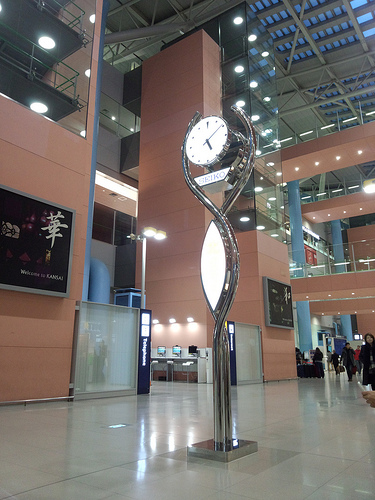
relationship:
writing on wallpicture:
[39, 203, 68, 256] [8, 187, 69, 295]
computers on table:
[158, 343, 203, 358] [154, 356, 197, 366]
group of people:
[296, 332, 374, 377] [294, 343, 373, 369]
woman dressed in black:
[358, 332, 372, 395] [355, 343, 374, 387]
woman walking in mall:
[358, 332, 372, 395] [1, 2, 367, 485]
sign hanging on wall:
[8, 187, 69, 295] [2, 97, 80, 402]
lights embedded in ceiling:
[235, 19, 278, 63] [117, 5, 374, 113]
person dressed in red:
[350, 342, 363, 374] [354, 343, 361, 369]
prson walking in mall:
[352, 342, 362, 374] [1, 2, 367, 485]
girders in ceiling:
[291, 68, 374, 97] [117, 5, 374, 113]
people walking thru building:
[294, 343, 373, 369] [1, 2, 367, 485]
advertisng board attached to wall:
[8, 187, 69, 295] [2, 97, 80, 402]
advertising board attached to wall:
[8, 187, 69, 295] [2, 97, 80, 402]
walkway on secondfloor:
[6, 35, 85, 108] [2, 48, 82, 91]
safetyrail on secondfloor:
[6, 35, 85, 108] [2, 48, 82, 91]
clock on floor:
[180, 116, 253, 166] [47, 406, 360, 481]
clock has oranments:
[180, 116, 253, 166] [195, 123, 235, 149]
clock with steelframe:
[180, 116, 253, 166] [185, 105, 246, 458]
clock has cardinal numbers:
[180, 116, 253, 166] [186, 125, 200, 162]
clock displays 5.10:
[180, 116, 253, 166] [204, 124, 223, 149]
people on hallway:
[294, 343, 373, 369] [154, 342, 336, 425]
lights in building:
[235, 19, 278, 63] [1, 2, 367, 485]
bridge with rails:
[300, 114, 367, 143] [280, 118, 364, 139]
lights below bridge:
[276, 157, 370, 178] [299, 190, 368, 219]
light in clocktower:
[208, 229, 219, 297] [180, 107, 262, 461]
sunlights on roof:
[264, 7, 363, 108] [117, 5, 374, 113]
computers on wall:
[158, 343, 203, 358] [147, 232, 204, 328]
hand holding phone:
[362, 391, 373, 403] [349, 371, 370, 394]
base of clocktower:
[187, 435, 267, 464] [180, 107, 262, 461]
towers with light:
[130, 314, 154, 388] [140, 315, 154, 336]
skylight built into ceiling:
[248, 1, 363, 123] [104, 2, 363, 185]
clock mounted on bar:
[180, 116, 253, 166] [178, 109, 251, 443]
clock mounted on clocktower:
[180, 116, 253, 166] [180, 107, 262, 461]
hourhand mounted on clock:
[205, 137, 213, 150] [182, 113, 232, 168]